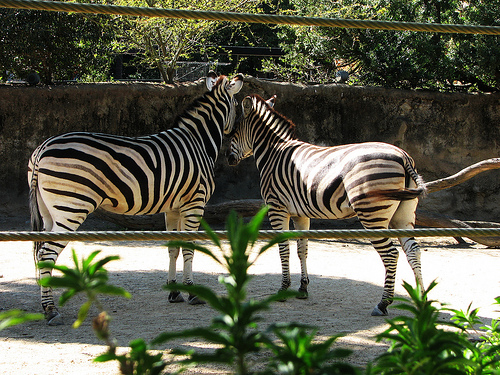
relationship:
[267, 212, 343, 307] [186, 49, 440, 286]
legs of a zebra